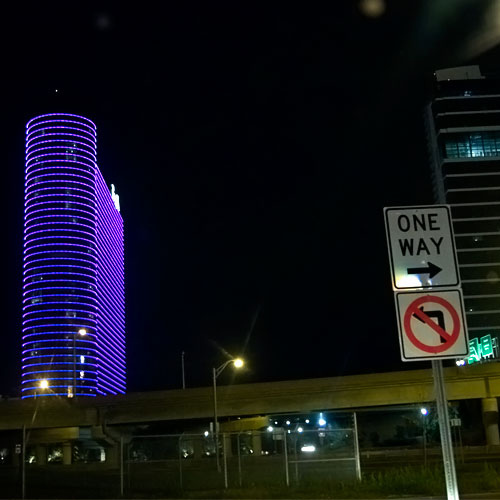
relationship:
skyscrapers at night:
[18, 105, 131, 399] [140, 62, 355, 222]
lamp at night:
[227, 356, 251, 376] [140, 62, 355, 222]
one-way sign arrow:
[384, 205, 465, 293] [402, 258, 449, 281]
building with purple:
[435, 68, 498, 363] [18, 105, 131, 399]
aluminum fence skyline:
[282, 432, 290, 488] [25, 55, 498, 158]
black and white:
[366, 40, 408, 87] [399, 294, 413, 308]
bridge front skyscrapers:
[0, 364, 499, 447] [18, 105, 131, 399]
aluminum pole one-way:
[282, 432, 290, 488] [396, 211, 449, 257]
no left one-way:
[403, 295, 463, 349] [396, 211, 449, 257]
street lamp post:
[12, 477, 497, 498] [209, 360, 263, 472]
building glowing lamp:
[435, 68, 498, 363] [227, 356, 251, 376]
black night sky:
[366, 40, 408, 87] [33, 23, 488, 50]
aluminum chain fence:
[282, 432, 290, 488] [122, 431, 361, 484]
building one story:
[435, 68, 498, 363] [25, 374, 126, 395]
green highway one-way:
[469, 337, 492, 362] [396, 211, 449, 257]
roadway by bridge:
[5, 356, 491, 406] [13, 364, 499, 386]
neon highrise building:
[30, 116, 92, 379] [435, 68, 498, 363]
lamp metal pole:
[222, 356, 278, 384] [209, 364, 230, 483]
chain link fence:
[148, 440, 178, 475] [122, 431, 361, 484]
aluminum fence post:
[278, 432, 293, 488] [209, 360, 263, 472]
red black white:
[403, 295, 463, 349] [399, 294, 413, 308]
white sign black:
[399, 294, 413, 308] [366, 40, 408, 87]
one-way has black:
[396, 211, 449, 257] [366, 40, 408, 87]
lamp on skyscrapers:
[227, 356, 251, 376] [18, 105, 131, 399]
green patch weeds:
[469, 337, 492, 362] [373, 466, 435, 494]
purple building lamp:
[30, 116, 92, 379] [227, 356, 251, 376]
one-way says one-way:
[396, 211, 449, 257] [384, 205, 465, 293]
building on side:
[435, 68, 498, 363] [94, 182, 130, 398]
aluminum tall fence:
[282, 432, 290, 488] [122, 431, 361, 484]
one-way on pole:
[396, 211, 449, 257] [209, 364, 230, 483]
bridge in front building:
[0, 364, 499, 447] [435, 68, 498, 363]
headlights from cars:
[299, 447, 317, 455] [182, 448, 276, 460]